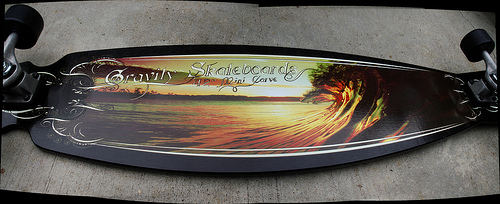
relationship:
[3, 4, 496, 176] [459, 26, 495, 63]
skateboard has wheel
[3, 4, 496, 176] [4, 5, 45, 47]
skateboard has wheel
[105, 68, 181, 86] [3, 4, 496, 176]
gravity word painted on skateboard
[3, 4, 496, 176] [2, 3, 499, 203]
skateboard on top of concrete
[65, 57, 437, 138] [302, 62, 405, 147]
design has cresting wave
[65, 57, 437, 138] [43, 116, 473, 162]
design has lower white border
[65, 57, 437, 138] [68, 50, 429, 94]
design has upper white boarder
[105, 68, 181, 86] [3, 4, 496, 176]
gravity word written on skateboard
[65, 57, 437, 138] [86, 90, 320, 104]
design has shore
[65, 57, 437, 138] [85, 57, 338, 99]
design has sky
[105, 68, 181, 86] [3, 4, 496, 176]
gravity word on skateboard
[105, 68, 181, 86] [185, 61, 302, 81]
gravity word next to skateboard word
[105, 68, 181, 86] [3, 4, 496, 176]
gravity word written on bottom of skateboard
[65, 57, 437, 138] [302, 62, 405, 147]
design of cresting wave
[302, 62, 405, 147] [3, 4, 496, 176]
cresting wave on underside of skateboard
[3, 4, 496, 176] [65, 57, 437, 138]
skateboard has design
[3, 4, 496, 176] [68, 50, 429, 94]
skateboard has upper white boarder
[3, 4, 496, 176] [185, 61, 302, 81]
skateboard has skateboard word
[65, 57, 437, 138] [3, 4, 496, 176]
design on skateboard